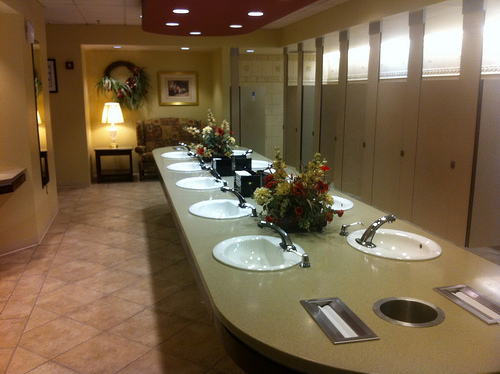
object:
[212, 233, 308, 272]
sink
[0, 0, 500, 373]
bathroom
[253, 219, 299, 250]
tap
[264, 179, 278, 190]
flower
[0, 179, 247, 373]
floor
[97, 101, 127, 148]
lamp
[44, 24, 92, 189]
wall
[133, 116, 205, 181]
couch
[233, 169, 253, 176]
towels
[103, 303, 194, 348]
tiles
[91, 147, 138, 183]
table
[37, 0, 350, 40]
ceiling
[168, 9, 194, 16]
lights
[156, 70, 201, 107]
frame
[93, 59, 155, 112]
wreath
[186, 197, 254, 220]
sink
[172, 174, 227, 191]
sink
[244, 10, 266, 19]
light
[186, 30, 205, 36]
light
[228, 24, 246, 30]
light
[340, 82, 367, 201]
stalls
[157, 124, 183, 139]
patterns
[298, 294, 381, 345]
dispenser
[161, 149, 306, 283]
row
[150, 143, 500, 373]
counter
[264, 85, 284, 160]
stall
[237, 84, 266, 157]
door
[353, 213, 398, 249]
faucet